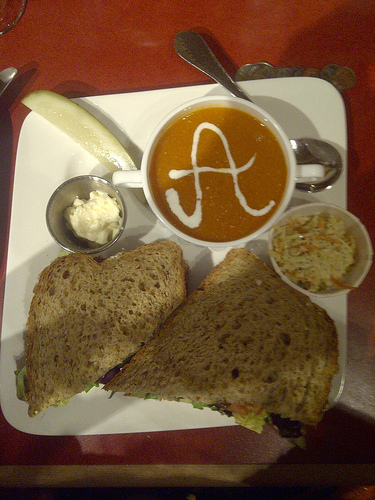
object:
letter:
[165, 122, 275, 229]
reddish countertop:
[0, 0, 374, 467]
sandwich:
[13, 238, 340, 451]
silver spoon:
[175, 29, 341, 192]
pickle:
[21, 89, 145, 206]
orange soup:
[149, 106, 288, 244]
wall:
[201, 40, 232, 83]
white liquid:
[164, 122, 275, 229]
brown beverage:
[149, 107, 287, 241]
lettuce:
[232, 402, 273, 436]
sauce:
[150, 105, 286, 244]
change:
[234, 62, 355, 91]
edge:
[25, 76, 344, 113]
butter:
[63, 190, 121, 249]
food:
[13, 108, 368, 450]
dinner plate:
[0, 75, 348, 437]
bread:
[27, 238, 190, 417]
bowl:
[268, 203, 373, 298]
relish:
[267, 214, 374, 294]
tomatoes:
[220, 402, 265, 415]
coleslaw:
[265, 210, 369, 292]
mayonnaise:
[63, 190, 125, 250]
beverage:
[148, 106, 288, 241]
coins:
[331, 66, 354, 91]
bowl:
[112, 95, 296, 248]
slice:
[20, 89, 146, 206]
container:
[45, 175, 127, 253]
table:
[0, 0, 375, 492]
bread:
[101, 248, 340, 428]